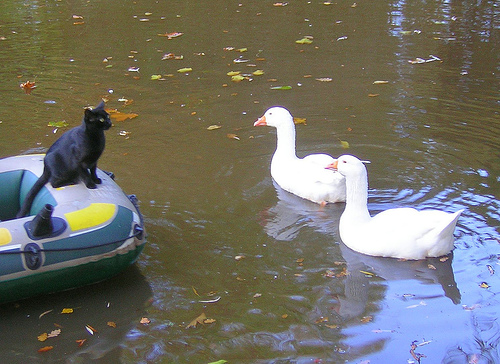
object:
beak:
[253, 115, 266, 127]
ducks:
[325, 154, 466, 261]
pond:
[319, 47, 460, 149]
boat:
[0, 153, 147, 304]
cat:
[17, 101, 113, 219]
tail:
[434, 209, 464, 237]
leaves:
[144, 12, 152, 16]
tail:
[17, 171, 52, 219]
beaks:
[324, 161, 338, 172]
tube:
[28, 204, 55, 236]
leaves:
[150, 74, 162, 80]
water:
[159, 272, 453, 351]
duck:
[253, 107, 371, 208]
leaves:
[177, 67, 193, 73]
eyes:
[99, 118, 105, 123]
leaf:
[270, 85, 293, 90]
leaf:
[253, 69, 266, 76]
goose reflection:
[259, 177, 334, 241]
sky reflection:
[376, 282, 492, 363]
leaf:
[360, 315, 373, 323]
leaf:
[185, 312, 207, 329]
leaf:
[107, 321, 117, 328]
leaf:
[139, 317, 150, 324]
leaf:
[75, 338, 86, 347]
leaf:
[427, 263, 436, 269]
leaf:
[48, 120, 70, 128]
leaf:
[281, 314, 288, 319]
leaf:
[61, 307, 74, 314]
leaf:
[110, 113, 138, 122]